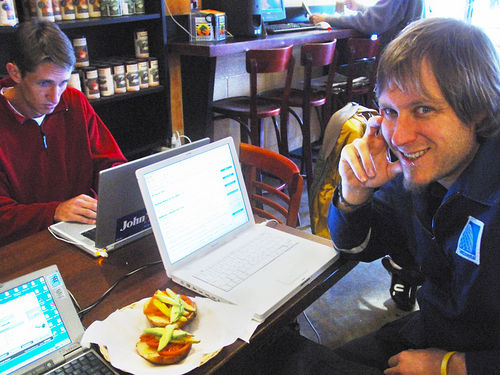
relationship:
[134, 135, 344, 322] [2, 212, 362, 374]
laptop on table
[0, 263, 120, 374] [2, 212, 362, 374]
laptop on table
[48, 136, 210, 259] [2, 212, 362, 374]
laptop on table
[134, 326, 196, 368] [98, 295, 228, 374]
toast on plate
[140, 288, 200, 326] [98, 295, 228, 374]
toast on plate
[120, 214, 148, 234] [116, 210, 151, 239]
"john" on sticker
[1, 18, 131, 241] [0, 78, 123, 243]
man wearing shirt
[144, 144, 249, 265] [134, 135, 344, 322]
screen on laptop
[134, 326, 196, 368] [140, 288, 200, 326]
toast next to toast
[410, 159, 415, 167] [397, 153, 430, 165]
piercing in lip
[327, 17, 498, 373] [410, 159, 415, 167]
man has piercing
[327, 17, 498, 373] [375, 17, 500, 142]
man has hair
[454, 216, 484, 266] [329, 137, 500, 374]
logo on jacket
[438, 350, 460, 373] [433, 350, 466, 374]
band on wrist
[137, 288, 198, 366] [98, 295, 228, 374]
food on plate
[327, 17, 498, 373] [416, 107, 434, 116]
man has eye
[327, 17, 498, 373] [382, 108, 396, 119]
man has eye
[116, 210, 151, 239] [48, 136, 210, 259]
sticker on laptop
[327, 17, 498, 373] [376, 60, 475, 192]
man has face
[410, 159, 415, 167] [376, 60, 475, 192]
piercing on face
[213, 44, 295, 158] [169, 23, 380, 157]
bar stool behind bar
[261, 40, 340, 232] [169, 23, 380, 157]
bar stool behind bar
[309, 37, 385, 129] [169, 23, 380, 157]
bar stool behind bar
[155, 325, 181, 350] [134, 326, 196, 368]
avocado on toast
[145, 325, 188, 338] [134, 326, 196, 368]
avocado on toast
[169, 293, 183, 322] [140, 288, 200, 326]
avocado on toast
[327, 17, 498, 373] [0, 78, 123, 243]
man wearing shirt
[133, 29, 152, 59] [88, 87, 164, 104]
jar on shelf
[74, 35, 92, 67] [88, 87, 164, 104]
jar on shelf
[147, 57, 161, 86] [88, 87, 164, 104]
jar on shelf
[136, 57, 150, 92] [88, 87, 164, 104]
jar on shelf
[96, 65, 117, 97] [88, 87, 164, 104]
jar on shelf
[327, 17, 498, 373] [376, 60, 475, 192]
man touching face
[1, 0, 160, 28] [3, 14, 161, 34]
tea on shelf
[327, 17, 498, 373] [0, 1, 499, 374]
man in coffee shop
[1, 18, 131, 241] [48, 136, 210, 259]
man using laptop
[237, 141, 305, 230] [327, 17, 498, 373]
chair behind man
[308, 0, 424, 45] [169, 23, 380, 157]
man sitting at bar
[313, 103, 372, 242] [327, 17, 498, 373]
rain jacket behind man